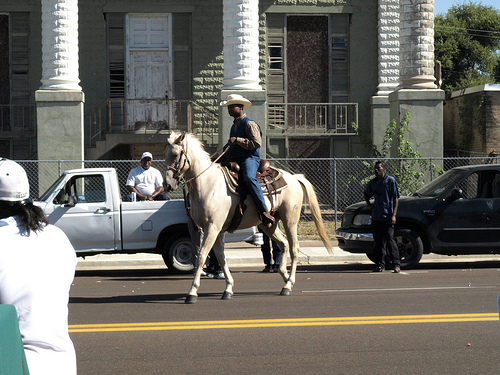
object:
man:
[215, 91, 280, 230]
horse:
[158, 124, 334, 305]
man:
[124, 149, 166, 203]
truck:
[28, 164, 268, 277]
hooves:
[186, 287, 294, 304]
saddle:
[221, 157, 288, 235]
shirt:
[125, 164, 165, 195]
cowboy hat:
[217, 93, 252, 106]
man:
[362, 157, 401, 272]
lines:
[69, 311, 500, 336]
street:
[69, 265, 500, 375]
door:
[123, 12, 177, 125]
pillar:
[398, 0, 437, 89]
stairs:
[79, 100, 129, 166]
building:
[1, 0, 446, 207]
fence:
[18, 156, 500, 246]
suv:
[335, 164, 500, 268]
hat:
[138, 151, 157, 161]